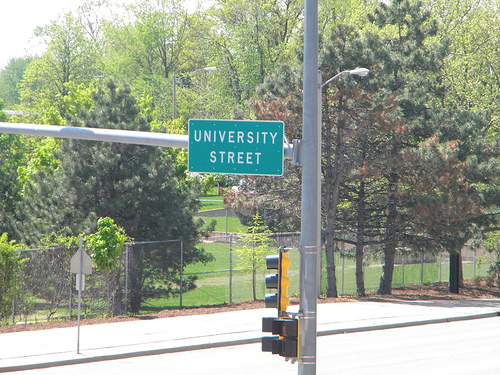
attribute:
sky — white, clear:
[32, 2, 68, 10]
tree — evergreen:
[253, 25, 296, 50]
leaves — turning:
[379, 39, 392, 66]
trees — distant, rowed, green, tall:
[123, 26, 171, 40]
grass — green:
[211, 285, 249, 296]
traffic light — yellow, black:
[249, 242, 303, 310]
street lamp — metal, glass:
[316, 60, 384, 95]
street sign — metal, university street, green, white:
[176, 104, 293, 180]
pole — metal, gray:
[60, 120, 116, 148]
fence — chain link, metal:
[207, 229, 252, 261]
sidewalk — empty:
[178, 318, 239, 335]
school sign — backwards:
[67, 240, 112, 275]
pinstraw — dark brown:
[435, 287, 449, 291]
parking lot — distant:
[214, 209, 215, 213]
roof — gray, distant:
[7, 101, 53, 117]